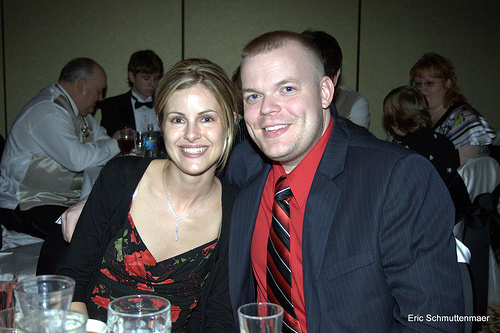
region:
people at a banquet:
[4, 26, 495, 331]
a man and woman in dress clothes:
[67, 32, 469, 332]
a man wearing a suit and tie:
[224, 130, 491, 331]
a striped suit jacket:
[227, 131, 474, 330]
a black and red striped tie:
[268, 178, 298, 331]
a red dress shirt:
[242, 155, 330, 332]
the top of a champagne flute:
[232, 295, 292, 332]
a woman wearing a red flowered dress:
[65, 158, 235, 331]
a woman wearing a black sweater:
[54, 152, 253, 330]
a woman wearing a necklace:
[156, 156, 226, 246]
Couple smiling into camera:
[56, 30, 466, 330]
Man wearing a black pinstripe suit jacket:
[228, 28, 465, 330]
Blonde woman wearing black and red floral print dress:
[53, 57, 233, 330]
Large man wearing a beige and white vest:
[0, 57, 122, 273]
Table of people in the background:
[5, 26, 495, 237]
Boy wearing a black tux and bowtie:
[96, 48, 163, 154]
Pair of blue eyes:
[244, 85, 299, 102]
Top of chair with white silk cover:
[461, 153, 497, 200]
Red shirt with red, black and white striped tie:
[248, 118, 333, 329]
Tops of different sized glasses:
[2, 275, 287, 330]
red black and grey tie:
[264, 164, 301, 331]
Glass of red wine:
[111, 128, 136, 156]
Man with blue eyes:
[223, 41, 475, 331]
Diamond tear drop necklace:
[151, 156, 218, 246]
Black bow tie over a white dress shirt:
[126, 91, 164, 138]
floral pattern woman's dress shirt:
[88, 200, 226, 332]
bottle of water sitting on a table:
[140, 120, 161, 160]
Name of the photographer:
[406, 310, 492, 325]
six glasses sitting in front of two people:
[0, 273, 288, 331]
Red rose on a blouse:
[121, 252, 148, 279]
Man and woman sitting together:
[90, 38, 492, 303]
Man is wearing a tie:
[245, 165, 353, 317]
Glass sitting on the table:
[98, 287, 142, 329]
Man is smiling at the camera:
[251, 110, 303, 146]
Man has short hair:
[230, 13, 327, 108]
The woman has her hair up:
[151, 48, 239, 202]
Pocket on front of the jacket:
[327, 243, 383, 307]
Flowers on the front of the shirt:
[100, 207, 242, 309]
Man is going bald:
[25, 28, 137, 122]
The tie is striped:
[259, 235, 314, 282]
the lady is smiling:
[176, 141, 211, 161]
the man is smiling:
[256, 120, 294, 137]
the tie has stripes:
[270, 216, 288, 261]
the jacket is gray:
[335, 192, 373, 222]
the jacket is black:
[99, 186, 116, 217]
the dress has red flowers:
[109, 243, 148, 279]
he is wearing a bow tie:
[132, 98, 158, 112]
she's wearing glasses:
[411, 78, 437, 91]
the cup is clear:
[27, 287, 62, 306]